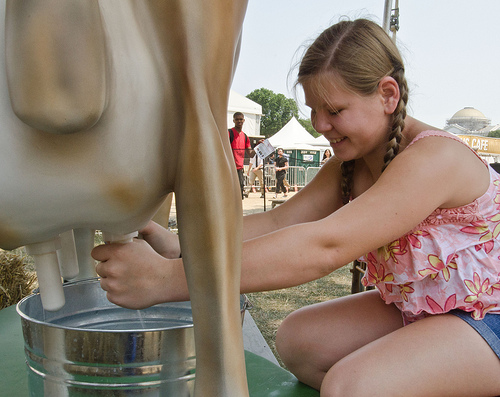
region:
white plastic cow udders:
[22, 205, 184, 306]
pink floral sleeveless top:
[348, 198, 486, 339]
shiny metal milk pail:
[30, 271, 220, 386]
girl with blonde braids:
[359, 108, 443, 213]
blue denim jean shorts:
[281, 296, 498, 388]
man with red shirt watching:
[224, 108, 261, 200]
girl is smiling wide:
[306, 107, 380, 177]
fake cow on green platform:
[6, 294, 348, 395]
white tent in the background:
[256, 110, 343, 162]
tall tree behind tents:
[251, 86, 308, 167]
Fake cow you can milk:
[4, 9, 493, 391]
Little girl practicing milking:
[130, 91, 470, 390]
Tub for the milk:
[27, 273, 227, 389]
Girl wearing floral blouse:
[340, 161, 499, 380]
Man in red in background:
[218, 108, 285, 219]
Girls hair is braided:
[300, 60, 449, 251]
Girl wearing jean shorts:
[352, 273, 491, 395]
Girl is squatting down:
[250, 67, 499, 358]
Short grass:
[275, 289, 307, 316]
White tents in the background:
[252, 107, 363, 222]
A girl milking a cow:
[98, 21, 498, 356]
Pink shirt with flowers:
[324, 157, 499, 339]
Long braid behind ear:
[383, 47, 412, 230]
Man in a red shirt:
[224, 104, 273, 222]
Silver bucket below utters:
[2, 258, 243, 391]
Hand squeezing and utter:
[73, 232, 180, 315]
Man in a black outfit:
[271, 138, 291, 201]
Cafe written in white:
[470, 131, 497, 156]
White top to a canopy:
[263, 111, 325, 156]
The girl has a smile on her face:
[290, 26, 419, 169]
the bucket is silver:
[10, 311, 214, 395]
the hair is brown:
[301, 23, 399, 84]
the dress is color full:
[362, 223, 497, 303]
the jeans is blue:
[468, 315, 498, 350]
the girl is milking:
[295, 150, 495, 395]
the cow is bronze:
[43, 20, 255, 291]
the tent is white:
[238, 92, 267, 124]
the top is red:
[233, 130, 250, 168]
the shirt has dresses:
[418, 231, 498, 303]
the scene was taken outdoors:
[2, 3, 496, 375]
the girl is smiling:
[289, 91, 400, 228]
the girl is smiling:
[280, 62, 482, 340]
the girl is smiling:
[239, 45, 347, 230]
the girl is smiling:
[299, 42, 414, 167]